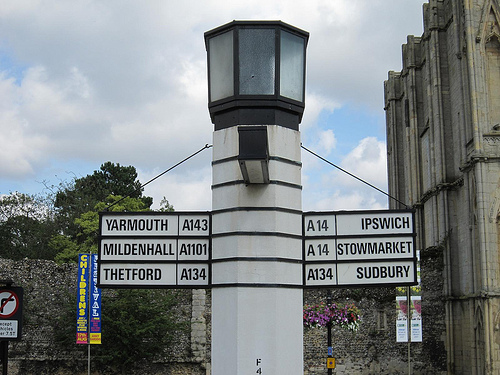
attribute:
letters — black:
[105, 215, 411, 286]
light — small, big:
[196, 19, 311, 130]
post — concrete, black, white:
[212, 124, 310, 375]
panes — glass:
[207, 32, 306, 100]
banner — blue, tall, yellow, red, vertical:
[73, 250, 113, 341]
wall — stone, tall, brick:
[3, 257, 435, 370]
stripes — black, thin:
[211, 158, 307, 292]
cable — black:
[92, 146, 411, 207]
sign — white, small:
[94, 211, 421, 283]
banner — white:
[392, 293, 428, 345]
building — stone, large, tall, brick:
[375, 0, 499, 375]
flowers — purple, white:
[299, 294, 367, 330]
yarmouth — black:
[96, 214, 182, 235]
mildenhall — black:
[97, 240, 180, 262]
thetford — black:
[101, 264, 167, 289]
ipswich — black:
[357, 214, 420, 234]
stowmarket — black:
[333, 237, 414, 262]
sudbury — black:
[354, 266, 419, 281]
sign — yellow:
[320, 355, 340, 374]